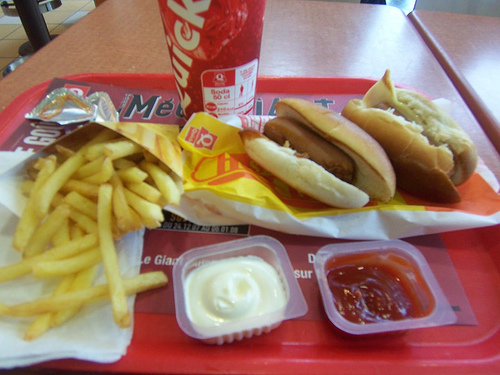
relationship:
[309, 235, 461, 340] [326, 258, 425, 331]
container of ketchup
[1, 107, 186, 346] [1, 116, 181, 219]
french fries in bag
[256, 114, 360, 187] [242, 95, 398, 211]
hotdog in bun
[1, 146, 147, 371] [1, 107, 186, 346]
napkins are under french fries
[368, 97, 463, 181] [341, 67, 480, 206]
hotdog in bun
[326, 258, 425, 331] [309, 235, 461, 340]
ketchup in container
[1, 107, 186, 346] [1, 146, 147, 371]
french fries on napkins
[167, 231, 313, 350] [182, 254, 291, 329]
packet has mayonnaise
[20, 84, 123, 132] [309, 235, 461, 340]
top of container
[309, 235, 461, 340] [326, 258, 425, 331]
container has ketchup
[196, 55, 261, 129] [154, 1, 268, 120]
tag on cup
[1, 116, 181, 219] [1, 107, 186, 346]
bag has french fries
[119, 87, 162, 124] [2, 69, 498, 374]
letter on tray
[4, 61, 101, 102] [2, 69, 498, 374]
edge of tray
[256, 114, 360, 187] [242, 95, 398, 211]
hotdog on bun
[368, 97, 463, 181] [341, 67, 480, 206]
hotdog on bun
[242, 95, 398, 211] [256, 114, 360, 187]
bun for hotdog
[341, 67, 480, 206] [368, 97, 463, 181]
bun for hotdog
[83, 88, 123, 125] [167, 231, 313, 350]
top of packet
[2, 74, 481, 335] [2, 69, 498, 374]
liner on tray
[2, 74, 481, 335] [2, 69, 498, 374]
liner on top of tray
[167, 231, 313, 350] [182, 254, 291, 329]
packet of mayonnaise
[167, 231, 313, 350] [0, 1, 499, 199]
packet on table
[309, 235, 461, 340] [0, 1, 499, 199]
container on table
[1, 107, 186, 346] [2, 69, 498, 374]
french fries are on tray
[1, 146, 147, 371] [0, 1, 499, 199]
napkins are on table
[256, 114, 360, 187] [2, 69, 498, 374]
hotdog on tray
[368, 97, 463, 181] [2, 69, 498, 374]
hotdog on tray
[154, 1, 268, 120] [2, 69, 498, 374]
beverage on tray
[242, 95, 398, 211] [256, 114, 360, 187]
bun holding hotdog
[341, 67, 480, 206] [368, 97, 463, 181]
bun holding hotdog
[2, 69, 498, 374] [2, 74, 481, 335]
tray has liner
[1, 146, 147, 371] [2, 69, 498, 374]
napkins are on tray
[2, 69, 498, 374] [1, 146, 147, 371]
tray has napkins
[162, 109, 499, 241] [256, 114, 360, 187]
bag for hotdog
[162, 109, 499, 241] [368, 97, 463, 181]
bag for hotdog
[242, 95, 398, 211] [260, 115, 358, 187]
bun has hotdog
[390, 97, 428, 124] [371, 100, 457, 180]
relish on hotdog